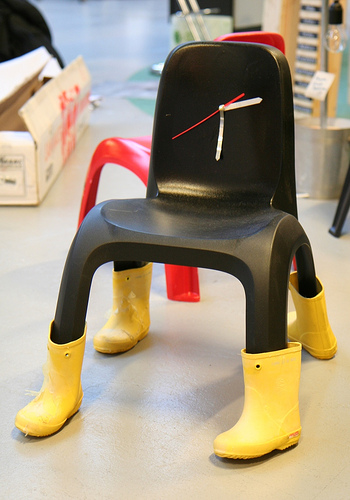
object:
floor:
[0, 105, 350, 498]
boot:
[212, 338, 304, 462]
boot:
[94, 260, 157, 354]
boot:
[12, 315, 87, 438]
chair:
[13, 38, 341, 464]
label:
[56, 85, 80, 162]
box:
[0, 45, 95, 205]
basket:
[294, 116, 348, 203]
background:
[0, 1, 350, 496]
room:
[0, 1, 350, 499]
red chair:
[78, 32, 288, 305]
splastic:
[101, 214, 197, 248]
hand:
[218, 93, 266, 112]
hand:
[214, 106, 226, 162]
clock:
[173, 69, 266, 169]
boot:
[285, 270, 341, 360]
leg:
[292, 226, 318, 297]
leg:
[114, 259, 149, 278]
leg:
[53, 237, 99, 345]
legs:
[241, 235, 291, 351]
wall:
[325, 50, 350, 168]